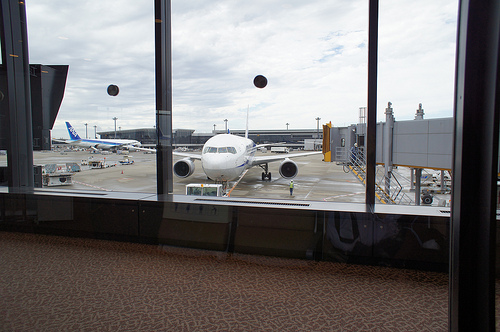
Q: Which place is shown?
A: It is an airport.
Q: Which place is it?
A: It is an airport.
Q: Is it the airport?
A: Yes, it is the airport.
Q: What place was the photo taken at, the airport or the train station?
A: It was taken at the airport.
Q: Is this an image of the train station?
A: No, the picture is showing the airport.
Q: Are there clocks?
A: No, there are no clocks.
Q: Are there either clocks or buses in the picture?
A: No, there are no clocks or buses.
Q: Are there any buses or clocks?
A: No, there are no clocks or buses.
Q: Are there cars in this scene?
A: No, there are no cars.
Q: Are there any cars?
A: No, there are no cars.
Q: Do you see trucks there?
A: No, there are no trucks.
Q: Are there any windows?
A: Yes, there is a window.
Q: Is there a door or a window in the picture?
A: Yes, there is a window.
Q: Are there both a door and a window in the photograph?
A: No, there is a window but no doors.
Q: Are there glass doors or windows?
A: Yes, there is a glass window.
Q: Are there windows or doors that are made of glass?
A: Yes, the window is made of glass.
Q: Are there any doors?
A: No, there are no doors.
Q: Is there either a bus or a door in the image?
A: No, there are no doors or buses.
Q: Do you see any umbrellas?
A: No, there are no umbrellas.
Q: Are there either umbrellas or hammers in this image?
A: No, there are no umbrellas or hammers.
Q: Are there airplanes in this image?
A: Yes, there is an airplane.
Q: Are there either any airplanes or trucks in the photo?
A: Yes, there is an airplane.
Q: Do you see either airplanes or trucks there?
A: Yes, there is an airplane.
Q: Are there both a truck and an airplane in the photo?
A: No, there is an airplane but no trucks.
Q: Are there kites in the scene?
A: No, there are no kites.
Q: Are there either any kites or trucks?
A: No, there are no kites or trucks.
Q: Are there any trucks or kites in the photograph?
A: No, there are no kites or trucks.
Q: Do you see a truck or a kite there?
A: No, there are no kites or trucks.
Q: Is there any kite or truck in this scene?
A: No, there are no kites or trucks.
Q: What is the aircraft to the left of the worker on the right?
A: The aircraft is an airplane.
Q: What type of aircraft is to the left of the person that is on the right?
A: The aircraft is an airplane.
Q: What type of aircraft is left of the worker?
A: The aircraft is an airplane.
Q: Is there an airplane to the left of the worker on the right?
A: Yes, there is an airplane to the left of the worker.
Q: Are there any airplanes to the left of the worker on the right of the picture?
A: Yes, there is an airplane to the left of the worker.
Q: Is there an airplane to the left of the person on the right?
A: Yes, there is an airplane to the left of the worker.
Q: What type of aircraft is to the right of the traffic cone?
A: The aircraft is an airplane.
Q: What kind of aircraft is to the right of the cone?
A: The aircraft is an airplane.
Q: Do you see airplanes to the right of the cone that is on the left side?
A: Yes, there is an airplane to the right of the cone.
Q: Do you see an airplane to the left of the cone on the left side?
A: No, the airplane is to the right of the cone.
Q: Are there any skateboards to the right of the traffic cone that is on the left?
A: No, there is an airplane to the right of the safety cone.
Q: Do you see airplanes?
A: Yes, there is an airplane.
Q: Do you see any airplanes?
A: Yes, there is an airplane.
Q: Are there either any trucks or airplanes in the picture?
A: Yes, there is an airplane.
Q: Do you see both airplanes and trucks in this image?
A: No, there is an airplane but no trucks.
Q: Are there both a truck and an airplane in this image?
A: No, there is an airplane but no trucks.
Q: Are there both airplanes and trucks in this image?
A: No, there is an airplane but no trucks.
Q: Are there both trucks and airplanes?
A: No, there is an airplane but no trucks.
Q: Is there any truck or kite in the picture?
A: No, there are no kites or trucks.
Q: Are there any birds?
A: No, there are no birds.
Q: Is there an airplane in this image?
A: Yes, there is an airplane.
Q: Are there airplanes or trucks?
A: Yes, there is an airplane.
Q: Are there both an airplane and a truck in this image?
A: No, there is an airplane but no trucks.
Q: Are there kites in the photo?
A: No, there are no kites.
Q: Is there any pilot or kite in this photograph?
A: No, there are no kites or pilots.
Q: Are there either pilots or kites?
A: No, there are no kites or pilots.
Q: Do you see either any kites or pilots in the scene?
A: No, there are no kites or pilots.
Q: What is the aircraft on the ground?
A: The aircraft is an airplane.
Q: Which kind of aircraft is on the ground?
A: The aircraft is an airplane.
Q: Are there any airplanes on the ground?
A: Yes, there is an airplane on the ground.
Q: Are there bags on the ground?
A: No, there is an airplane on the ground.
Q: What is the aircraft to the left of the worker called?
A: The aircraft is an airplane.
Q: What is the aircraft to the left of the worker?
A: The aircraft is an airplane.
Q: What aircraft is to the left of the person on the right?
A: The aircraft is an airplane.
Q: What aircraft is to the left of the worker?
A: The aircraft is an airplane.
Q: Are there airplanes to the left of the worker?
A: Yes, there is an airplane to the left of the worker.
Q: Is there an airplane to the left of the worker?
A: Yes, there is an airplane to the left of the worker.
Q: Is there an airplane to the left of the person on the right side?
A: Yes, there is an airplane to the left of the worker.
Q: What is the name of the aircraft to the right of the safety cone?
A: The aircraft is an airplane.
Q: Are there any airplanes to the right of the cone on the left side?
A: Yes, there is an airplane to the right of the safety cone.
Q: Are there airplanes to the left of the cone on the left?
A: No, the airplane is to the right of the cone.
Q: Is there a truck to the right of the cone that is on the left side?
A: No, there is an airplane to the right of the cone.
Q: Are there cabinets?
A: No, there are no cabinets.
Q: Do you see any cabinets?
A: No, there are no cabinets.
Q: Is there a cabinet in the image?
A: No, there are no cabinets.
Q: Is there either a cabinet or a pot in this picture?
A: No, there are no cabinets or pots.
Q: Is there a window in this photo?
A: Yes, there is a window.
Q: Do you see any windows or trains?
A: Yes, there is a window.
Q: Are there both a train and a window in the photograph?
A: No, there is a window but no trains.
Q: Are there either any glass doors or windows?
A: Yes, there is a glass window.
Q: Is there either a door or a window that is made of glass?
A: Yes, the window is made of glass.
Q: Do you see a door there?
A: No, there are no doors.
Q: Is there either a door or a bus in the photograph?
A: No, there are no doors or buses.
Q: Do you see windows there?
A: Yes, there is a window.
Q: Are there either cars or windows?
A: Yes, there is a window.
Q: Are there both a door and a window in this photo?
A: No, there is a window but no doors.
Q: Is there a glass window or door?
A: Yes, there is a glass window.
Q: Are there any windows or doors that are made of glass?
A: Yes, the window is made of glass.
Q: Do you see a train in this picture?
A: No, there are no trains.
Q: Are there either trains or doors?
A: No, there are no trains or doors.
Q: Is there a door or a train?
A: No, there are no trains or doors.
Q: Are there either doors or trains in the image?
A: No, there are no trains or doors.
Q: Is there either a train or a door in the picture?
A: No, there are no trains or doors.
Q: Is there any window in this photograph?
A: Yes, there is a window.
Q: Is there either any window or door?
A: Yes, there is a window.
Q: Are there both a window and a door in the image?
A: No, there is a window but no doors.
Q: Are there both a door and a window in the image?
A: No, there is a window but no doors.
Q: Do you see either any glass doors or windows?
A: Yes, there is a glass window.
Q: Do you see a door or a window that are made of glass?
A: Yes, the window is made of glass.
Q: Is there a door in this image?
A: No, there are no doors.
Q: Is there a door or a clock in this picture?
A: No, there are no doors or clocks.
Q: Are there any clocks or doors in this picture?
A: No, there are no doors or clocks.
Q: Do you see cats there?
A: No, there are no cats.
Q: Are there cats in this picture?
A: No, there are no cats.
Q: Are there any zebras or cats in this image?
A: No, there are no cats or zebras.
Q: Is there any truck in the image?
A: No, there are no trucks.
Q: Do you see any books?
A: No, there are no books.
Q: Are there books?
A: No, there are no books.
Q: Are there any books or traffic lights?
A: No, there are no books or traffic lights.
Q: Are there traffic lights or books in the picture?
A: No, there are no books or traffic lights.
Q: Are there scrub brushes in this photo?
A: No, there are no scrub brushes.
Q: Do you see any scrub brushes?
A: No, there are no scrub brushes.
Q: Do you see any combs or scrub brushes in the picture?
A: No, there are no scrub brushes or combs.